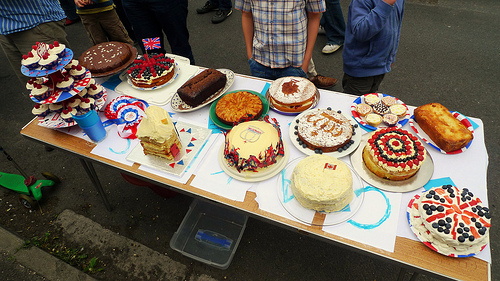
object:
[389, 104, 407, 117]
cupcakes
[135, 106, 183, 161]
layered cake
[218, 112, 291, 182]
cake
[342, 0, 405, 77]
blue shirt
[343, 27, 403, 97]
person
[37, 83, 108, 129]
platters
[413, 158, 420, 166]
strawberries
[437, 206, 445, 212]
blueberries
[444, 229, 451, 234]
balls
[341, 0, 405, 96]
person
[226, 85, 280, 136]
wall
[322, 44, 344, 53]
shoe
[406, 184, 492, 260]
cake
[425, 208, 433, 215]
blueberries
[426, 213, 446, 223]
red stripes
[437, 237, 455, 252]
white icing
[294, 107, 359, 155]
cake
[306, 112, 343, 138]
crown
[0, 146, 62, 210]
scooter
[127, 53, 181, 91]
cake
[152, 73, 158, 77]
berries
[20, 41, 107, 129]
cupcakes tower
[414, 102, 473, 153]
bread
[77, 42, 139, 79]
cake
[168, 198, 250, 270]
box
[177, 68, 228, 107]
dessert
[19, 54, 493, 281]
table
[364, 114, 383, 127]
cookies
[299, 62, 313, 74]
hands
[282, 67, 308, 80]
pockets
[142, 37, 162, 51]
flag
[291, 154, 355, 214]
cake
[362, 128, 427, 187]
cake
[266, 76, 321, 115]
cake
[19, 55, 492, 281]
table top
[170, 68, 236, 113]
plate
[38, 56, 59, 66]
icing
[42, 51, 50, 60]
berries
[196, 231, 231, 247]
label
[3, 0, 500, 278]
ground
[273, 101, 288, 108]
sprinkles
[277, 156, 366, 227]
plate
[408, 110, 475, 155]
plates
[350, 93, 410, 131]
plate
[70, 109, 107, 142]
item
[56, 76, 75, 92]
muffins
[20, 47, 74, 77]
platter